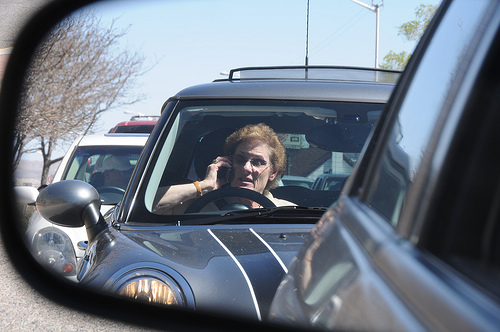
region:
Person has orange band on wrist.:
[178, 170, 213, 200]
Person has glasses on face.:
[232, 147, 300, 189]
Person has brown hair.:
[205, 115, 345, 185]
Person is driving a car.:
[151, 166, 321, 239]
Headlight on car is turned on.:
[112, 253, 202, 319]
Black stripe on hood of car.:
[214, 217, 289, 302]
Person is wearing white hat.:
[96, 155, 135, 176]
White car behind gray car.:
[66, 117, 148, 226]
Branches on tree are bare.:
[43, 101, 93, 135]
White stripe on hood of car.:
[214, 229, 256, 317]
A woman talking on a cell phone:
[166, 107, 303, 219]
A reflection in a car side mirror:
[64, 10, 455, 327]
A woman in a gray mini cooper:
[28, 37, 445, 308]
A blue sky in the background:
[158, 12, 285, 57]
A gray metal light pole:
[363, 8, 384, 62]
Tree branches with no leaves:
[58, 30, 133, 111]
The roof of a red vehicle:
[110, 107, 164, 134]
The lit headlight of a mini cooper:
[93, 252, 206, 314]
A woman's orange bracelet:
[188, 175, 212, 201]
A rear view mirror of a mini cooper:
[298, 115, 388, 155]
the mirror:
[103, 56, 370, 329]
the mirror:
[24, 13, 294, 323]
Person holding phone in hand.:
[212, 146, 249, 218]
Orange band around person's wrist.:
[183, 170, 220, 233]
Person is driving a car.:
[188, 139, 295, 252]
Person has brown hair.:
[232, 117, 287, 151]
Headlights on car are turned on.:
[124, 260, 187, 330]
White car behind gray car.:
[55, 134, 157, 176]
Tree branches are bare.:
[41, 48, 146, 115]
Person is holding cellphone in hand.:
[203, 158, 264, 210]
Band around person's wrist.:
[191, 169, 213, 214]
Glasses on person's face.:
[222, 151, 288, 197]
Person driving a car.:
[176, 154, 316, 242]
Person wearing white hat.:
[98, 151, 145, 193]